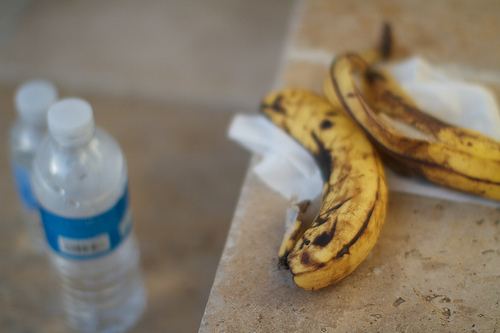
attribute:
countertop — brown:
[215, 193, 499, 313]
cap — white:
[13, 77, 60, 122]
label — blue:
[27, 183, 147, 260]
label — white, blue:
[35, 178, 137, 264]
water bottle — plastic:
[29, 96, 149, 331]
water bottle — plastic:
[10, 79, 58, 255]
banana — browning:
[263, 87, 385, 290]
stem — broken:
[233, 113, 313, 248]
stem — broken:
[368, 30, 498, 140]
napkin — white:
[220, 47, 498, 217]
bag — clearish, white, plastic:
[226, 49, 499, 214]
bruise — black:
[299, 124, 344, 155]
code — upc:
[56, 233, 109, 255]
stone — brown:
[196, 2, 498, 332]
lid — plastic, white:
[45, 96, 97, 149]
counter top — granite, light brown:
[200, 4, 498, 331]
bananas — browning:
[251, 48, 498, 298]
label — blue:
[27, 175, 135, 261]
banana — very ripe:
[320, 22, 498, 195]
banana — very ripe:
[258, 83, 390, 293]